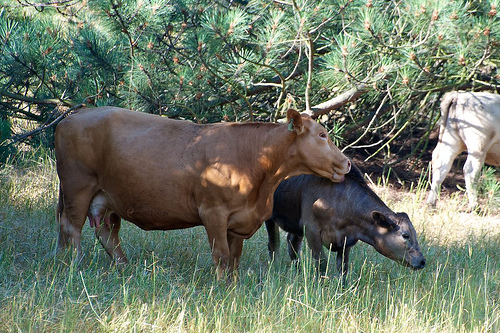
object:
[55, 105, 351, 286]
cow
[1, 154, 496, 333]
field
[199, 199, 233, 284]
leg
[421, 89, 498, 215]
cow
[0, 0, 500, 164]
tree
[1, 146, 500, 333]
grass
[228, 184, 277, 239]
haunch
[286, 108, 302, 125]
ear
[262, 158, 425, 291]
cow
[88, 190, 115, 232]
udders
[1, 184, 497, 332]
shadows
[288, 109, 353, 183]
head